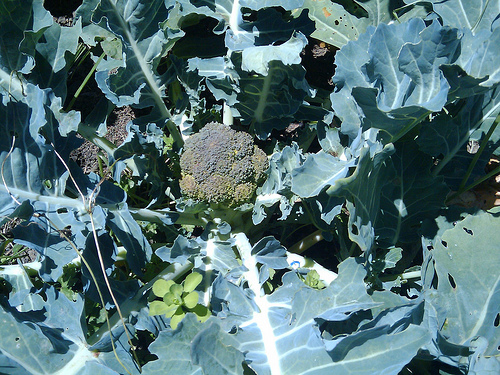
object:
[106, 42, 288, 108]
leaves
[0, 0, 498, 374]
leaves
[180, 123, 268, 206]
broccoli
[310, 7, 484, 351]
leaves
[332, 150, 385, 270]
leaves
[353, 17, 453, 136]
leaves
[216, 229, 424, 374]
leaves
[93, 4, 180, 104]
leaves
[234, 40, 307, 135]
leaves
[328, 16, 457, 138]
leaf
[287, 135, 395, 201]
leaf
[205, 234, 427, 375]
leaf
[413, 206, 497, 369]
leaf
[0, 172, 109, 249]
leaf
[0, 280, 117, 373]
leaves